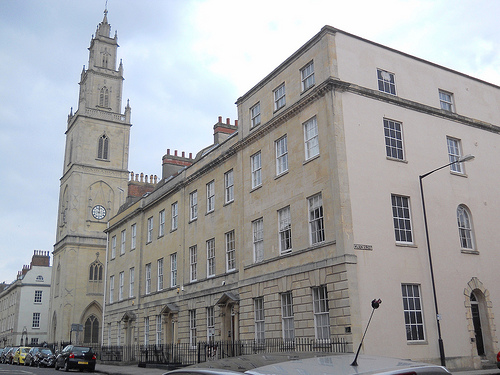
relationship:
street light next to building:
[416, 152, 478, 374] [96, 16, 498, 374]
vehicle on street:
[51, 343, 99, 374] [1, 357, 116, 374]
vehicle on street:
[22, 345, 58, 367] [1, 357, 116, 374]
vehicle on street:
[11, 345, 30, 365] [1, 357, 116, 374]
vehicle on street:
[3, 344, 19, 365] [1, 357, 116, 374]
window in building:
[390, 189, 417, 251] [96, 16, 498, 374]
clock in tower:
[90, 202, 110, 223] [42, 0, 134, 362]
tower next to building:
[42, 0, 134, 362] [96, 16, 498, 374]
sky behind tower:
[0, 1, 498, 285] [42, 0, 134, 362]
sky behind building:
[0, 1, 498, 285] [96, 16, 498, 374]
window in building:
[381, 114, 409, 163] [96, 16, 498, 374]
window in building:
[375, 65, 400, 97] [96, 16, 498, 374]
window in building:
[455, 205, 481, 256] [96, 16, 498, 374]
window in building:
[446, 136, 466, 179] [96, 16, 498, 374]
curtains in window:
[306, 117, 319, 159] [300, 111, 322, 162]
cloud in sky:
[183, 2, 435, 89] [0, 1, 498, 285]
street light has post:
[416, 152, 478, 374] [419, 176, 447, 367]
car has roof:
[150, 295, 451, 375] [165, 345, 443, 375]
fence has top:
[67, 331, 352, 372] [83, 337, 353, 350]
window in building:
[249, 214, 268, 267] [96, 16, 498, 374]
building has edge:
[96, 16, 498, 374] [330, 77, 500, 137]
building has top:
[96, 16, 498, 374] [232, 22, 499, 139]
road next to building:
[1, 357, 116, 374] [96, 16, 498, 374]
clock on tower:
[90, 202, 110, 223] [42, 0, 134, 362]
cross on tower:
[101, 0, 111, 14] [42, 0, 134, 362]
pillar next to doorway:
[232, 306, 242, 360] [226, 303, 236, 362]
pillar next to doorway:
[219, 305, 226, 361] [226, 303, 236, 362]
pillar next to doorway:
[171, 317, 177, 365] [168, 312, 173, 363]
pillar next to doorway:
[161, 317, 168, 359] [168, 312, 173, 363]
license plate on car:
[76, 359, 90, 369] [51, 343, 99, 374]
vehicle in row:
[51, 343, 99, 374] [1, 341, 103, 372]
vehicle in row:
[22, 345, 58, 367] [1, 341, 103, 372]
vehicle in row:
[11, 345, 30, 365] [1, 341, 103, 372]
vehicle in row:
[3, 344, 19, 365] [1, 341, 103, 372]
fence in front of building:
[67, 331, 352, 372] [96, 16, 498, 374]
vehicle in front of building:
[51, 343, 99, 374] [96, 16, 498, 374]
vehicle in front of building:
[22, 345, 58, 367] [96, 16, 498, 374]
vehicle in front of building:
[3, 344, 19, 365] [96, 16, 498, 374]